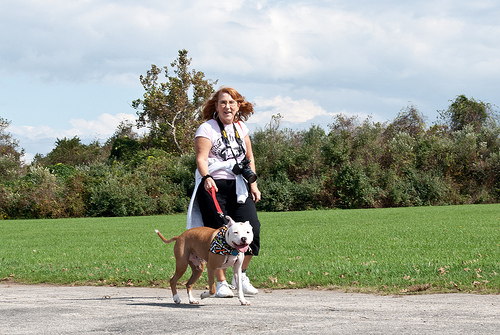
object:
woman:
[191, 86, 262, 296]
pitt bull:
[153, 214, 255, 306]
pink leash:
[206, 187, 225, 214]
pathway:
[1, 283, 499, 334]